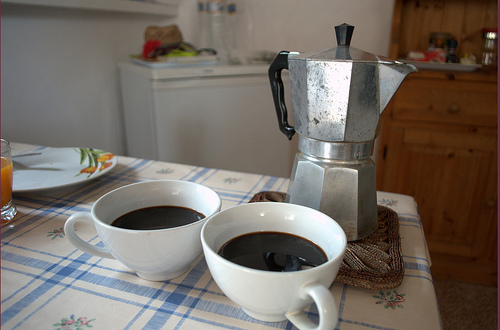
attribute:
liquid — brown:
[235, 217, 292, 255]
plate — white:
[11, 145, 117, 191]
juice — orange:
[2, 157, 12, 207]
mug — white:
[62, 179, 220, 283]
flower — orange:
[83, 151, 114, 171]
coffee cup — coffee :
[193, 198, 353, 329]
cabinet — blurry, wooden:
[377, 3, 497, 286]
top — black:
[327, 27, 359, 57]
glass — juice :
[0, 135, 15, 223]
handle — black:
[268, 49, 298, 139]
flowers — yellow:
[67, 130, 139, 197]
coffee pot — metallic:
[247, 16, 438, 295]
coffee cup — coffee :
[202, 186, 342, 326]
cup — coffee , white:
[65, 171, 220, 286]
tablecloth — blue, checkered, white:
[0, 138, 437, 328]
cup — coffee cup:
[43, 161, 220, 291]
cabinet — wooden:
[395, 67, 499, 188]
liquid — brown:
[217, 231, 327, 271]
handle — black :
[266, 43, 299, 147]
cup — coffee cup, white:
[200, 200, 348, 328]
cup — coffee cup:
[65, 178, 220, 280]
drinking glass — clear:
[0, 133, 30, 228]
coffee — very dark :
[219, 225, 326, 270]